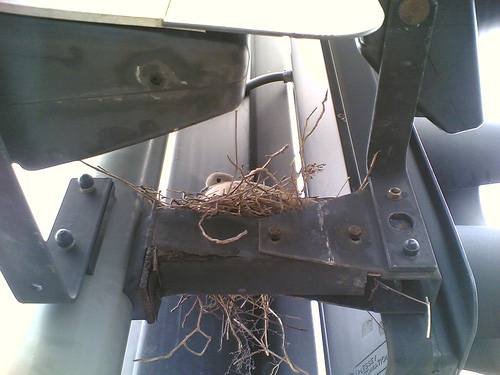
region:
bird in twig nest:
[111, 60, 340, 366]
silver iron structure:
[18, 2, 497, 366]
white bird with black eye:
[193, 168, 300, 206]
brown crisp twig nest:
[97, 81, 348, 361]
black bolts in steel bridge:
[53, 170, 438, 256]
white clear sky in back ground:
[6, 127, 192, 369]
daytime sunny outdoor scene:
[3, 0, 498, 365]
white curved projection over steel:
[3, 4, 388, 56]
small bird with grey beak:
[196, 166, 321, 202]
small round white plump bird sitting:
[195, 170, 310, 207]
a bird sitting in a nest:
[187, 166, 283, 215]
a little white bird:
[195, 166, 232, 192]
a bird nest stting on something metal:
[110, 164, 300, 217]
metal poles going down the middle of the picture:
[93, 55, 393, 374]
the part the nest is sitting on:
[148, 207, 396, 294]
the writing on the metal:
[338, 347, 385, 374]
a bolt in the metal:
[63, 172, 98, 199]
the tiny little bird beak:
[196, 185, 208, 193]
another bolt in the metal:
[400, 237, 419, 253]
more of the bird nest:
[167, 299, 289, 374]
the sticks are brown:
[99, 154, 356, 248]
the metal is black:
[290, 219, 437, 266]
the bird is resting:
[192, 165, 284, 219]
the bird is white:
[188, 164, 270, 215]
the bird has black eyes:
[182, 160, 296, 218]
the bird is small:
[187, 153, 292, 215]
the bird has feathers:
[192, 159, 289, 222]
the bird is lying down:
[189, 159, 287, 209]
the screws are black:
[400, 232, 427, 262]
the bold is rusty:
[383, 183, 408, 201]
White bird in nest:
[202, 168, 317, 208]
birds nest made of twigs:
[151, 178, 315, 218]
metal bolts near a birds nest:
[78, 173, 99, 194]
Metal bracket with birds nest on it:
[139, 193, 443, 315]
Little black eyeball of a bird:
[214, 176, 223, 184]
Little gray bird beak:
[198, 185, 208, 194]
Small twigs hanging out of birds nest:
[168, 298, 285, 374]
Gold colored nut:
[386, 186, 403, 198]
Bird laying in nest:
[176, 170, 320, 212]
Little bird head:
[201, 171, 233, 188]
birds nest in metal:
[152, 140, 338, 355]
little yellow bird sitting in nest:
[194, 160, 299, 205]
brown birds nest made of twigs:
[143, 128, 330, 355]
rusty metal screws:
[326, 205, 376, 257]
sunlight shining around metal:
[437, 26, 499, 244]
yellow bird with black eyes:
[191, 154, 314, 203]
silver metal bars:
[12, 112, 130, 314]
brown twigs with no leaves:
[155, 126, 330, 363]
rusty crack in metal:
[136, 236, 248, 278]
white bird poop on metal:
[306, 182, 346, 272]